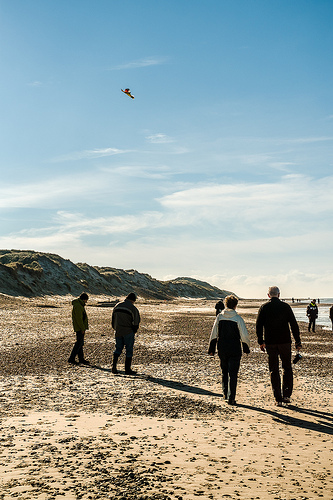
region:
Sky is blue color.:
[184, 32, 272, 95]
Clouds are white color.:
[184, 186, 324, 280]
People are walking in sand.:
[63, 276, 324, 432]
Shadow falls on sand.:
[61, 341, 331, 456]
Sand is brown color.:
[154, 432, 254, 480]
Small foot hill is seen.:
[8, 250, 211, 298]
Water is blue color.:
[293, 298, 327, 327]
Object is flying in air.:
[118, 84, 139, 103]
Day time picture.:
[3, 4, 313, 485]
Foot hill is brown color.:
[11, 256, 211, 298]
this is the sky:
[7, 19, 78, 62]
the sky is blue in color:
[202, 19, 318, 115]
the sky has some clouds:
[169, 186, 318, 262]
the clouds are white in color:
[186, 190, 312, 229]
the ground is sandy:
[163, 423, 237, 472]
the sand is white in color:
[126, 421, 136, 430]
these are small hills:
[3, 249, 224, 295]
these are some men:
[61, 283, 326, 403]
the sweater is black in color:
[269, 307, 286, 335]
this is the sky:
[44, 27, 220, 64]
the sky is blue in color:
[217, 30, 274, 82]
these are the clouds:
[181, 186, 270, 209]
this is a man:
[250, 285, 306, 403]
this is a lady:
[205, 286, 251, 407]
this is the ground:
[73, 389, 257, 486]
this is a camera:
[293, 351, 307, 367]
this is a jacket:
[115, 305, 139, 331]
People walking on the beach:
[52, 280, 326, 417]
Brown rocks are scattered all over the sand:
[35, 299, 295, 489]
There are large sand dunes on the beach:
[12, 255, 211, 301]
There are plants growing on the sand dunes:
[7, 246, 226, 305]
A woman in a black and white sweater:
[202, 289, 261, 415]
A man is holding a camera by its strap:
[249, 287, 309, 410]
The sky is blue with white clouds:
[189, 259, 328, 296]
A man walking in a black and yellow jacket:
[302, 295, 328, 334]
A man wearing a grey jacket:
[108, 290, 156, 379]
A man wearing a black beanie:
[66, 292, 98, 365]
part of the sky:
[194, 26, 232, 76]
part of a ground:
[169, 446, 203, 483]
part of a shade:
[252, 399, 275, 422]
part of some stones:
[89, 450, 111, 472]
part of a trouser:
[224, 367, 245, 399]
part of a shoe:
[125, 366, 136, 371]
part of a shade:
[275, 407, 297, 438]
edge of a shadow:
[171, 381, 195, 388]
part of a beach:
[170, 440, 200, 482]